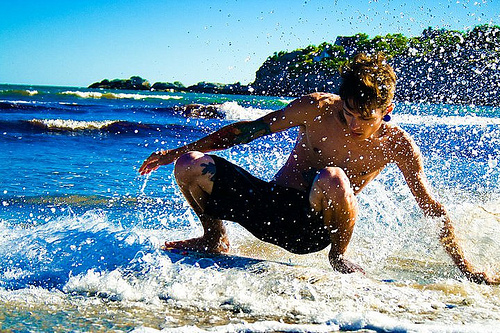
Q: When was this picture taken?
A: During the day.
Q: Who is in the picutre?
A: A boy.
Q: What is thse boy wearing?
A: Short.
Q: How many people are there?
A: 1.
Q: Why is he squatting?
A: He's surfing.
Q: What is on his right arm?
A: A tattoo.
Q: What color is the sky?
A: Blue.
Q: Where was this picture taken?
A: On the water.